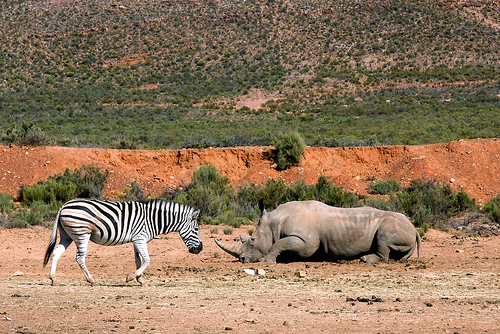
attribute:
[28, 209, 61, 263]
tail — black, white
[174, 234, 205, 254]
nose — black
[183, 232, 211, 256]
mouth — black